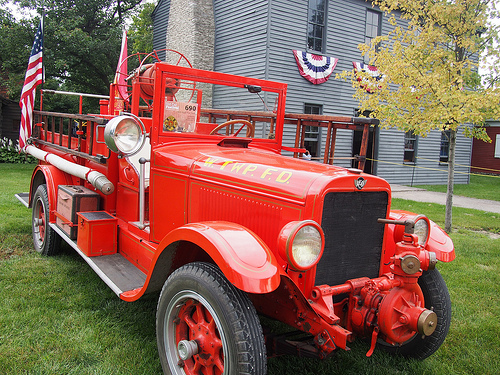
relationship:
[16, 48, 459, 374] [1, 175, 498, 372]
firetruck on grass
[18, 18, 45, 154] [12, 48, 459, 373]
flag on truck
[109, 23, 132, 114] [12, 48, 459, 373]
flag on truck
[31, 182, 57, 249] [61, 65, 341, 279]
wheel on firetruck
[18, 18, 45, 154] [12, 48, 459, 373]
flag in back of truck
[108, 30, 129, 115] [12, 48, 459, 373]
flag in back of truck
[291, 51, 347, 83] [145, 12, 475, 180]
banner on building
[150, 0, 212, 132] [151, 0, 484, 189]
fire place on building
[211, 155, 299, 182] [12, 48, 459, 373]
letters on truck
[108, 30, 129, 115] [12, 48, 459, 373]
flag on back of truck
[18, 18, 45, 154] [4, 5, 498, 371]
flag hanging outside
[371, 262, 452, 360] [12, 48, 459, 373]
tire on truck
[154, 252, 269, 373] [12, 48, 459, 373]
tire on truck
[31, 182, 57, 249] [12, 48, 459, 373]
wheel on truck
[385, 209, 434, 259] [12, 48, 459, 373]
light on truck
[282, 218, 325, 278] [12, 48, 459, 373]
light on truck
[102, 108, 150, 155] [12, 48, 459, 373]
light on truck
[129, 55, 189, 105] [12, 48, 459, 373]
hose on truck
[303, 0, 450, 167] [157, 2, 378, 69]
window on building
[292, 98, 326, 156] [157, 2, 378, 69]
window on building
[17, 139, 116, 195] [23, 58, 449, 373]
fire hose attached to fire truck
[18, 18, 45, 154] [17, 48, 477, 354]
flag on truck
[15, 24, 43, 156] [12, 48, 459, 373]
flag on truck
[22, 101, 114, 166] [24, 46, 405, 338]
ladder hanging on side of truck